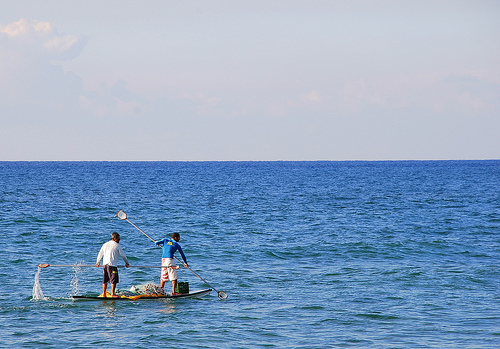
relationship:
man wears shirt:
[157, 235, 189, 299] [156, 238, 188, 261]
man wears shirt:
[95, 232, 130, 299] [94, 241, 128, 270]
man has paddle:
[157, 235, 189, 299] [116, 206, 230, 302]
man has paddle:
[95, 232, 130, 299] [38, 254, 192, 274]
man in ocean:
[157, 235, 189, 299] [1, 159, 499, 345]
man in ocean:
[95, 232, 130, 299] [1, 159, 499, 345]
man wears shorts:
[95, 232, 130, 299] [99, 267, 119, 284]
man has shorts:
[157, 235, 189, 299] [158, 256, 178, 284]